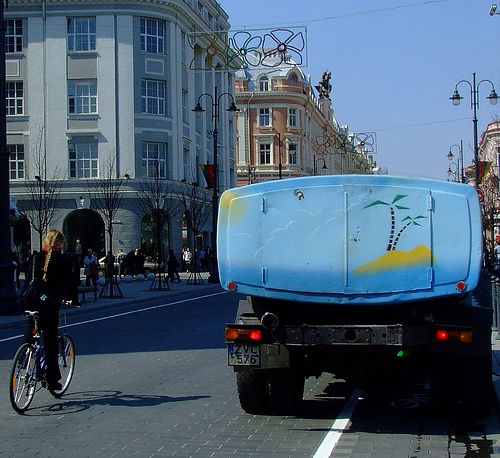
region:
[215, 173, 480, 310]
back of a blue truck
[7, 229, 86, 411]
a woman on a bike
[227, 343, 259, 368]
license plate on a truck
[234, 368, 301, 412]
rear wheels on a truck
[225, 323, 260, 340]
tail light of a truck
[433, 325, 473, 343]
tail light of a truck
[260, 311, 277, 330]
exhaust on a truck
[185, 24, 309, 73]
a banner with flowers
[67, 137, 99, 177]
a window on a building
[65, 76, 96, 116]
a window on a building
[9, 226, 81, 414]
a girl is riding a bike on the street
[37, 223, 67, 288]
the girl has blonde hair in a braid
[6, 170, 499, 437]
the bike rider is passing a truck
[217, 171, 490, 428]
the truck has its brake lights on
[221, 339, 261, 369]
the tag on the truck is black and white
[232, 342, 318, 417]
the truck has dual tires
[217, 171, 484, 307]
the back of the truck is blue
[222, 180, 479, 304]
an island scene is painted on the truck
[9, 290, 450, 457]
the street has gray pavers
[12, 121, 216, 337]
bare trees are in protective base cages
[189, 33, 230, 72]
yellow flower on sign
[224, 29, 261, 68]
blue flower on sign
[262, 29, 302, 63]
red flower on sign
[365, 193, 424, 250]
palm trees on truck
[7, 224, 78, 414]
girl on a bike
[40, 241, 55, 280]
girl has pony tale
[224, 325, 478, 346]
break lights are red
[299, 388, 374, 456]
line on road is white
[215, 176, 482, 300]
back of truck is blue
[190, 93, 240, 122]
street lights are off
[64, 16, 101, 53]
White window on building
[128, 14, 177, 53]
White window on building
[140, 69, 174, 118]
White window on building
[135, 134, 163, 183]
White window on building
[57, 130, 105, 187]
White window on building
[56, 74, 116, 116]
White window on building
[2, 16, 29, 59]
White window on building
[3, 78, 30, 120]
White window on building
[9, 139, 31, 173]
White window on building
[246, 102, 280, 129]
White window on building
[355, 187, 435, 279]
sand and palms painted on rear of truck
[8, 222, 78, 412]
girl on bicycle rides past the truck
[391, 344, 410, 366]
green rear light on truck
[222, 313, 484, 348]
rear lights are glowing red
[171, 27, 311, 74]
flowers that will light up at night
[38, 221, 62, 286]
long blond braid on black coat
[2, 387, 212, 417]
shadow on the street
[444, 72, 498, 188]
street lights with two lamps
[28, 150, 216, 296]
young trees along the street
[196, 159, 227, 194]
banner on the light post